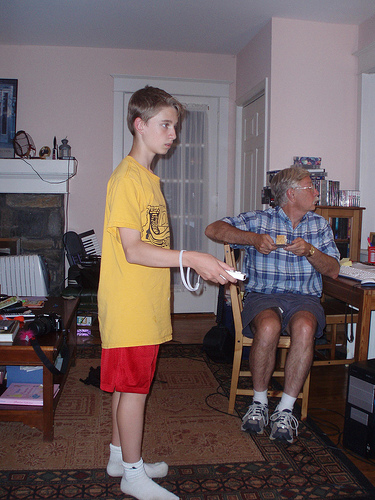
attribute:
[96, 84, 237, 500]
boy — playing, young, looking, standing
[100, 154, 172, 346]
shirt — yellow, blue plaid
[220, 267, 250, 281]
wii remote — white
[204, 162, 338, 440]
man — sitting, old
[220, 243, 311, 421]
chair — wooden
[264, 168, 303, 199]
hair — grey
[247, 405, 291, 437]
shoes — grey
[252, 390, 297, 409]
socks — white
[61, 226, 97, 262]
keyboard — black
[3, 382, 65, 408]
book — sitting, pink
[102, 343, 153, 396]
shorts — red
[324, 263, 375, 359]
table — brown, wooden